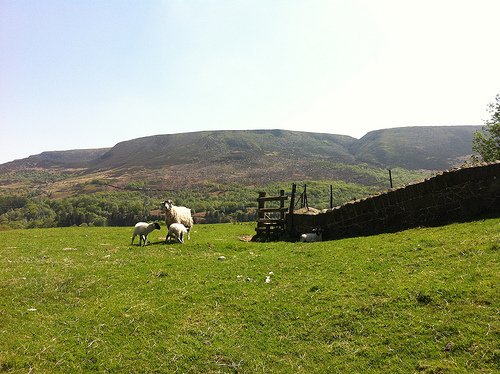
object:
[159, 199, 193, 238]
sheep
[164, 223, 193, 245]
sheep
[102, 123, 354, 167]
mountains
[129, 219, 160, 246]
sheep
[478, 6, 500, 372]
right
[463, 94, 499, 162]
tree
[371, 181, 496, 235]
wall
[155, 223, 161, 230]
black face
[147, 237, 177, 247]
shadow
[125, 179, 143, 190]
trees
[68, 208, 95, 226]
tree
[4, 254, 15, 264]
plant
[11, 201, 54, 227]
bush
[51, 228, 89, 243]
ground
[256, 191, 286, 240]
fence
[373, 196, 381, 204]
rocks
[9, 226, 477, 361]
pasture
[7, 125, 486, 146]
horizon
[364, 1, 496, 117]
sky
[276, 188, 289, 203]
cross bars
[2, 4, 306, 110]
sky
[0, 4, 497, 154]
background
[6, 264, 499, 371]
field